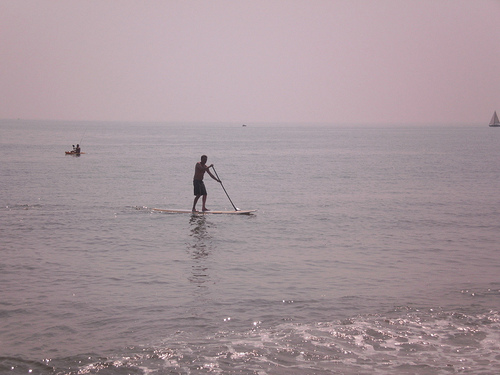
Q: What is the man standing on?
A: Paddle board.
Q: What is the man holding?
A: Paddle.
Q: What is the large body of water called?
A: Ocean.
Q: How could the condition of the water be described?
A: Calm.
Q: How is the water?
A: Calm.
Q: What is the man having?
A: Paddle.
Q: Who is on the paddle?
A: A man.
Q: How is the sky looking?
A: Gray and fuzzy.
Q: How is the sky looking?
A: Smoky and gray.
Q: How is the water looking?
A: Very calm.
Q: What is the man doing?
A: In water.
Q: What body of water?
A: Ocean.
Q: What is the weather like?
A: Overcast.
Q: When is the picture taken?
A: Daytime.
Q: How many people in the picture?
A: Two.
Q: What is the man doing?
A: Paddle surfing.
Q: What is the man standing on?
A: A surfboard.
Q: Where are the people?
A: In the water.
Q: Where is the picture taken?
A: On the beach.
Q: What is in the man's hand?
A: A paddle.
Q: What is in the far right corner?
A: A boat.